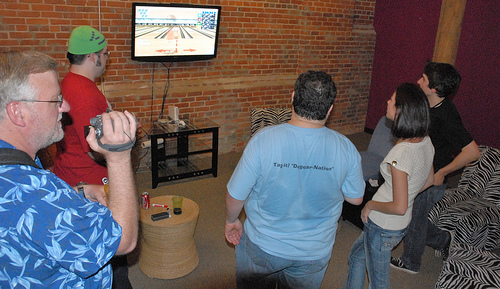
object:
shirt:
[0, 133, 123, 285]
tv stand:
[138, 117, 218, 188]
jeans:
[401, 180, 452, 269]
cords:
[149, 61, 174, 119]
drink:
[169, 195, 184, 214]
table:
[139, 193, 200, 280]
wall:
[365, 1, 499, 149]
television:
[130, 1, 222, 59]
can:
[149, 211, 169, 223]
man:
[36, 22, 135, 287]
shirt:
[38, 70, 113, 183]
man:
[1, 49, 144, 287]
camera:
[85, 110, 139, 159]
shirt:
[227, 123, 369, 255]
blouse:
[370, 138, 437, 231]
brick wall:
[0, 0, 375, 168]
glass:
[169, 195, 185, 214]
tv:
[129, 3, 222, 63]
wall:
[3, 1, 375, 171]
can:
[140, 188, 152, 209]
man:
[223, 70, 364, 287]